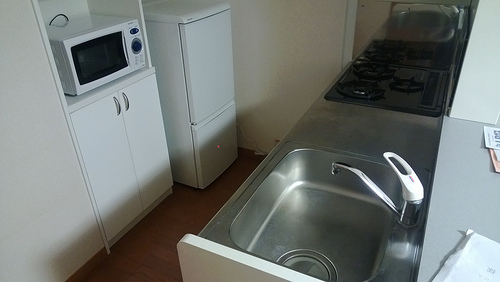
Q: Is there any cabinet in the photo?
A: Yes, there is a cabinet.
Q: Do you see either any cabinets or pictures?
A: Yes, there is a cabinet.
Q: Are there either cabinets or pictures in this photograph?
A: Yes, there is a cabinet.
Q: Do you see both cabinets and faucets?
A: Yes, there are both a cabinet and a faucet.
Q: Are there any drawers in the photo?
A: No, there are no drawers.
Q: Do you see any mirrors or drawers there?
A: No, there are no drawers or mirrors.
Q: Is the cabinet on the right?
A: No, the cabinet is on the left of the image.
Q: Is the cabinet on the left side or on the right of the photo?
A: The cabinet is on the left of the image.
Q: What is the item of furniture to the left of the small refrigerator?
A: The piece of furniture is a cabinet.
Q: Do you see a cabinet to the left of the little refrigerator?
A: Yes, there is a cabinet to the left of the refrigerator.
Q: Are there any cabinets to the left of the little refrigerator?
A: Yes, there is a cabinet to the left of the refrigerator.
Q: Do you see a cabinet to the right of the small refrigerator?
A: No, the cabinet is to the left of the fridge.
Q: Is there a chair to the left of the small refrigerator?
A: No, there is a cabinet to the left of the fridge.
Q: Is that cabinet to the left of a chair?
A: No, the cabinet is to the left of a refrigerator.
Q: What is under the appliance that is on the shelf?
A: The cabinet is under the microwave.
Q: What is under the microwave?
A: The cabinet is under the microwave.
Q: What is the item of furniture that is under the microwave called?
A: The piece of furniture is a cabinet.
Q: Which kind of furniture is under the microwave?
A: The piece of furniture is a cabinet.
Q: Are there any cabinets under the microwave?
A: Yes, there is a cabinet under the microwave.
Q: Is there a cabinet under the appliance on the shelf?
A: Yes, there is a cabinet under the microwave.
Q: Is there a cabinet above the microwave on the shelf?
A: No, the cabinet is under the microwave.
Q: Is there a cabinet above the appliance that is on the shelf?
A: No, the cabinet is under the microwave.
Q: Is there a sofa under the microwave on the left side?
A: No, there is a cabinet under the microwave.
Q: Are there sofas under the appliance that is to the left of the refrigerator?
A: No, there is a cabinet under the microwave.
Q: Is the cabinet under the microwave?
A: Yes, the cabinet is under the microwave.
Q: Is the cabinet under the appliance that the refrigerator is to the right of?
A: Yes, the cabinet is under the microwave.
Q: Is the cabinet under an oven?
A: No, the cabinet is under the microwave.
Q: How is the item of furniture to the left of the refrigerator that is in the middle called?
A: The piece of furniture is a cabinet.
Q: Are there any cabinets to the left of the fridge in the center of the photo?
A: Yes, there is a cabinet to the left of the fridge.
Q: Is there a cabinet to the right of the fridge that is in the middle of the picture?
A: No, the cabinet is to the left of the refrigerator.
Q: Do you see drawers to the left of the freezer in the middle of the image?
A: No, there is a cabinet to the left of the fridge.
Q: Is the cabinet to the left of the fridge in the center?
A: Yes, the cabinet is to the left of the fridge.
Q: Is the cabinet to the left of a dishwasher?
A: No, the cabinet is to the left of the fridge.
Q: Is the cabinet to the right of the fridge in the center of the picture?
A: No, the cabinet is to the left of the fridge.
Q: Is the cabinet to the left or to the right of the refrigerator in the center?
A: The cabinet is to the left of the refrigerator.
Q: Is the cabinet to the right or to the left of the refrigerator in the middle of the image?
A: The cabinet is to the left of the refrigerator.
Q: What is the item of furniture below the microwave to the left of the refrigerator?
A: The piece of furniture is a cabinet.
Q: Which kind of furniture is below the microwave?
A: The piece of furniture is a cabinet.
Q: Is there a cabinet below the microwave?
A: Yes, there is a cabinet below the microwave.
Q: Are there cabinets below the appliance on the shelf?
A: Yes, there is a cabinet below the microwave.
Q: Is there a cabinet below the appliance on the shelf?
A: Yes, there is a cabinet below the microwave.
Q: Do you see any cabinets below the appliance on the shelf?
A: Yes, there is a cabinet below the microwave.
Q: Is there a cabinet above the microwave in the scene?
A: No, the cabinet is below the microwave.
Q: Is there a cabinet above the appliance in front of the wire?
A: No, the cabinet is below the microwave.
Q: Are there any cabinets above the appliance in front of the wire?
A: No, the cabinet is below the microwave.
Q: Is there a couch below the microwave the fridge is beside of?
A: No, there is a cabinet below the microwave.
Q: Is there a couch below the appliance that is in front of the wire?
A: No, there is a cabinet below the microwave.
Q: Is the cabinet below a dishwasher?
A: No, the cabinet is below the microwave.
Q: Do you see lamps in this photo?
A: No, there are no lamps.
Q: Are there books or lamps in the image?
A: No, there are no lamps or books.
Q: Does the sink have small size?
A: Yes, the sink is small.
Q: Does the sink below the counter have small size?
A: Yes, the sink is small.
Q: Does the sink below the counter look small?
A: Yes, the sink is small.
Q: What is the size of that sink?
A: The sink is small.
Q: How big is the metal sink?
A: The sink is small.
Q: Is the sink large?
A: No, the sink is small.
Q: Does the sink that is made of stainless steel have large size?
A: No, the sink is small.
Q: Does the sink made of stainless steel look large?
A: No, the sink is small.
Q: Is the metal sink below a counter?
A: Yes, the sink is below a counter.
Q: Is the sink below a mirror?
A: No, the sink is below a counter.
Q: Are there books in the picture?
A: No, there are no books.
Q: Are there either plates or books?
A: No, there are no books or plates.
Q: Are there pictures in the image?
A: No, there are no pictures.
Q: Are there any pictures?
A: No, there are no pictures.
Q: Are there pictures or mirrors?
A: No, there are no pictures or mirrors.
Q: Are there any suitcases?
A: No, there are no suitcases.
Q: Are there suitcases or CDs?
A: No, there are no suitcases or cds.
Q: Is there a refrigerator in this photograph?
A: Yes, there is a refrigerator.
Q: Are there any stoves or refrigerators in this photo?
A: Yes, there is a refrigerator.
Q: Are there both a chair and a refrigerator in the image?
A: No, there is a refrigerator but no chairs.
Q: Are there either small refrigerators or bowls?
A: Yes, there is a small refrigerator.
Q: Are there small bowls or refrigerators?
A: Yes, there is a small refrigerator.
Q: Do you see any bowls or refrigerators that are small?
A: Yes, the refrigerator is small.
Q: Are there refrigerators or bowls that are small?
A: Yes, the refrigerator is small.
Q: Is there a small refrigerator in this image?
A: Yes, there is a small refrigerator.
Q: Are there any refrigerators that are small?
A: Yes, there is a refrigerator that is small.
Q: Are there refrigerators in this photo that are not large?
A: Yes, there is a small refrigerator.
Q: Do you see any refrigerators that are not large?
A: Yes, there is a small refrigerator.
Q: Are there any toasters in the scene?
A: No, there are no toasters.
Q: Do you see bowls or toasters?
A: No, there are no toasters or bowls.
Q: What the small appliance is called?
A: The appliance is a refrigerator.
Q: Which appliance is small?
A: The appliance is a refrigerator.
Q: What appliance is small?
A: The appliance is a refrigerator.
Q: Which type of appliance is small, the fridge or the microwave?
A: The fridge is small.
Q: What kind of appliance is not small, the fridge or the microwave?
A: The microwave is not small.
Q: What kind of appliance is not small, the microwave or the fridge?
A: The microwave is not small.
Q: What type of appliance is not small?
A: The appliance is a microwave.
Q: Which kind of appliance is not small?
A: The appliance is a microwave.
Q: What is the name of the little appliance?
A: The appliance is a refrigerator.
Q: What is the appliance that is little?
A: The appliance is a refrigerator.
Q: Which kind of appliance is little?
A: The appliance is a refrigerator.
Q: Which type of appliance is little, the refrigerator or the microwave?
A: The refrigerator is little.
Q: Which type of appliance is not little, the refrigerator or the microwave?
A: The microwave is not little.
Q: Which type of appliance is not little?
A: The appliance is a microwave.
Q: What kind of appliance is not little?
A: The appliance is a microwave.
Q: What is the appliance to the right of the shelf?
A: The appliance is a refrigerator.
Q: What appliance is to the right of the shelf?
A: The appliance is a refrigerator.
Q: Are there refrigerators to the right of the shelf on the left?
A: Yes, there is a refrigerator to the right of the shelf.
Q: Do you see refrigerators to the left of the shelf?
A: No, the refrigerator is to the right of the shelf.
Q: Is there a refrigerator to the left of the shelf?
A: No, the refrigerator is to the right of the shelf.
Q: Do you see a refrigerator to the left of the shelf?
A: No, the refrigerator is to the right of the shelf.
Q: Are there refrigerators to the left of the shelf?
A: No, the refrigerator is to the right of the shelf.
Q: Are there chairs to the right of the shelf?
A: No, there is a refrigerator to the right of the shelf.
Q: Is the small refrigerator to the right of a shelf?
A: Yes, the refrigerator is to the right of a shelf.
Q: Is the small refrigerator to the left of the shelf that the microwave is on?
A: No, the fridge is to the right of the shelf.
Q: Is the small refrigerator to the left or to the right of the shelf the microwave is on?
A: The fridge is to the right of the shelf.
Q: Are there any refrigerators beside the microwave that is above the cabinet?
A: Yes, there is a refrigerator beside the microwave.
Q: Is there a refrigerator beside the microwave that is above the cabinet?
A: Yes, there is a refrigerator beside the microwave.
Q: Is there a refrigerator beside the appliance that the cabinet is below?
A: Yes, there is a refrigerator beside the microwave.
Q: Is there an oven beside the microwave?
A: No, there is a refrigerator beside the microwave.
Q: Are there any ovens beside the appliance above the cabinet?
A: No, there is a refrigerator beside the microwave.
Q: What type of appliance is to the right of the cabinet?
A: The appliance is a refrigerator.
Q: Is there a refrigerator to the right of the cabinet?
A: Yes, there is a refrigerator to the right of the cabinet.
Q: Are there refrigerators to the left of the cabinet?
A: No, the refrigerator is to the right of the cabinet.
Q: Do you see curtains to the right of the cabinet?
A: No, there is a refrigerator to the right of the cabinet.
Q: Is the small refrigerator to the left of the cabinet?
A: No, the refrigerator is to the right of the cabinet.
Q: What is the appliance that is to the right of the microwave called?
A: The appliance is a refrigerator.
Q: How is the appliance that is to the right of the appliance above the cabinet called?
A: The appliance is a refrigerator.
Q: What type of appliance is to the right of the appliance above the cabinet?
A: The appliance is a refrigerator.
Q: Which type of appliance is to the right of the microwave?
A: The appliance is a refrigerator.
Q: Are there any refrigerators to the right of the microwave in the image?
A: Yes, there is a refrigerator to the right of the microwave.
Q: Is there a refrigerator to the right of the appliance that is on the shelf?
A: Yes, there is a refrigerator to the right of the microwave.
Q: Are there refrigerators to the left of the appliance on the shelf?
A: No, the refrigerator is to the right of the microwave.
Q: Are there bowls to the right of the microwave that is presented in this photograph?
A: No, there is a refrigerator to the right of the microwave.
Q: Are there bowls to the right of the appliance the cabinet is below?
A: No, there is a refrigerator to the right of the microwave.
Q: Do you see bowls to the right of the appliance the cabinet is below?
A: No, there is a refrigerator to the right of the microwave.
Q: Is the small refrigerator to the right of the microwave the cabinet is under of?
A: Yes, the freezer is to the right of the microwave.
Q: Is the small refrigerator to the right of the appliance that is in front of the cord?
A: Yes, the freezer is to the right of the microwave.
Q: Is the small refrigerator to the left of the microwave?
A: No, the fridge is to the right of the microwave.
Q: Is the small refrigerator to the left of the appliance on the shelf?
A: No, the fridge is to the right of the microwave.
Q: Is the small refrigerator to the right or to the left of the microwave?
A: The fridge is to the right of the microwave.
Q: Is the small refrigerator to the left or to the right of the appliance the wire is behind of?
A: The fridge is to the right of the microwave.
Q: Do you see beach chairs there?
A: No, there are no beach chairs.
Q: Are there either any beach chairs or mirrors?
A: No, there are no beach chairs or mirrors.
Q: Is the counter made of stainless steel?
A: Yes, the counter is made of stainless steel.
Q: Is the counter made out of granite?
A: No, the counter is made of stainless steel.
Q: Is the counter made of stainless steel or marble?
A: The counter is made of stainless steel.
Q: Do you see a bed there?
A: No, there are no beds.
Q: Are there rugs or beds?
A: No, there are no beds or rugs.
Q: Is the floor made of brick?
A: Yes, the floor is made of brick.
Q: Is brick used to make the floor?
A: Yes, the floor is made of brick.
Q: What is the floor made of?
A: The floor is made of brick.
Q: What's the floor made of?
A: The floor is made of brick.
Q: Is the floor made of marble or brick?
A: The floor is made of brick.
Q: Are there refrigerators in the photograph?
A: Yes, there is a refrigerator.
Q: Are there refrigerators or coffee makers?
A: Yes, there is a refrigerator.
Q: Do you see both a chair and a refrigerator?
A: No, there is a refrigerator but no chairs.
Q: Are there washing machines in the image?
A: No, there are no washing machines.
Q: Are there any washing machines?
A: No, there are no washing machines.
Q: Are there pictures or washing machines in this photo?
A: No, there are no washing machines or pictures.